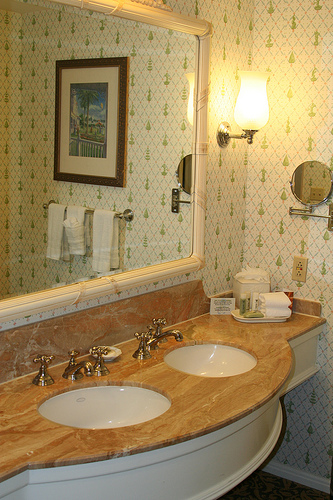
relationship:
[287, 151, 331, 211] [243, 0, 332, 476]
mirror hanging on wall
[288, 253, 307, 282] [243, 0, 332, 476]
outlet on wall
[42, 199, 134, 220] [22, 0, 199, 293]
towel bar on wall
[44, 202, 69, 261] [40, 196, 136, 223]
towel on towel bar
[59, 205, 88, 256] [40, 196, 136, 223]
towel on towel bar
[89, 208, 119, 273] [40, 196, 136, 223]
towel on towel bar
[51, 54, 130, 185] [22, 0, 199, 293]
frame hanging on wall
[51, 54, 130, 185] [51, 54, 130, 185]
frame has frame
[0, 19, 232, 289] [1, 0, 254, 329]
mirror on wall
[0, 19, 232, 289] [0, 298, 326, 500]
mirror above counter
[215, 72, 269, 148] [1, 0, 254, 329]
lamp on wall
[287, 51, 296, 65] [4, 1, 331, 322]
tree on wallpaper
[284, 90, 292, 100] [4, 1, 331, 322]
tree on wallpaper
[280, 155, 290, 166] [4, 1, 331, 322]
tree on wallpaper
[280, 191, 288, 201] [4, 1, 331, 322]
tree on wallpaper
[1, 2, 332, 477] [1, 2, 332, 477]
wall on wall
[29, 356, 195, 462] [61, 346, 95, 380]
sink with faucet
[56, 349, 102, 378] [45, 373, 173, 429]
faucet head of a sink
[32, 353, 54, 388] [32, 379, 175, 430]
fixture for a sink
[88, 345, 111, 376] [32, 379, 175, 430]
fixture for a sink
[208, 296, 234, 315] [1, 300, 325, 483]
card mounted on counter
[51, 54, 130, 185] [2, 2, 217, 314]
frame reflected from mirror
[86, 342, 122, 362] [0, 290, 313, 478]
soap dish on counter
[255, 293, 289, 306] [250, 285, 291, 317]
towels on rack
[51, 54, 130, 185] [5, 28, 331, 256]
frame on wall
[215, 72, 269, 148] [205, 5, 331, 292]
lamp on wall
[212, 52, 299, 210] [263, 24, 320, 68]
lamp on walls